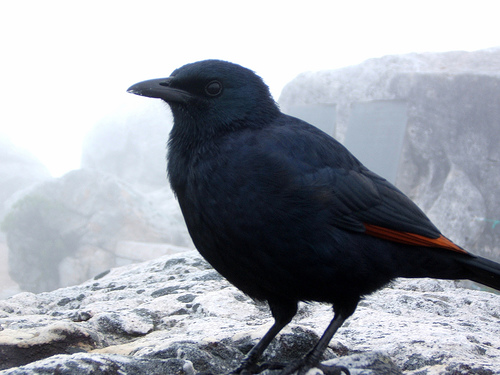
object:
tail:
[449, 252, 500, 293]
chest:
[166, 128, 253, 245]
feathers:
[320, 185, 354, 216]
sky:
[0, 0, 500, 180]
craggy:
[274, 47, 499, 265]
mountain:
[0, 48, 500, 295]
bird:
[126, 59, 500, 375]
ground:
[0, 257, 500, 374]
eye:
[203, 79, 223, 97]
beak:
[127, 76, 199, 109]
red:
[442, 239, 449, 245]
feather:
[348, 168, 381, 201]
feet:
[252, 356, 352, 375]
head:
[123, 59, 278, 140]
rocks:
[0, 314, 324, 375]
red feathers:
[361, 223, 433, 248]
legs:
[304, 301, 358, 364]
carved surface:
[278, 47, 499, 298]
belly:
[180, 196, 282, 304]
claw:
[296, 360, 314, 375]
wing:
[248, 114, 473, 259]